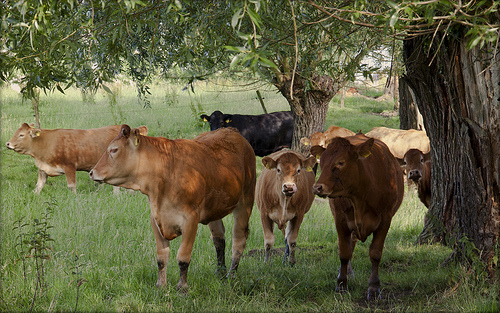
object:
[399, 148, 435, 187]
head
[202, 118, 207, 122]
tags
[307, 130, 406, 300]
brown cow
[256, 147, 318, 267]
brown cow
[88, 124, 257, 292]
brown cow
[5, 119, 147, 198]
brown cow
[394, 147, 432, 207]
brown cow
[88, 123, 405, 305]
three cows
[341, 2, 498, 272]
tree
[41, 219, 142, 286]
grass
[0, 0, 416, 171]
tree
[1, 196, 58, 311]
weeds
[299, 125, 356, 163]
cow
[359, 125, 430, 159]
cow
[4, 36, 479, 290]
pasture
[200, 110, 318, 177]
black cow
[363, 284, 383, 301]
hoof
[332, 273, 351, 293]
hoof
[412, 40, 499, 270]
tree trunk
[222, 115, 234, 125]
ear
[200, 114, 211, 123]
ear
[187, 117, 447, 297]
camera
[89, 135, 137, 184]
face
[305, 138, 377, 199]
head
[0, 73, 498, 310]
field